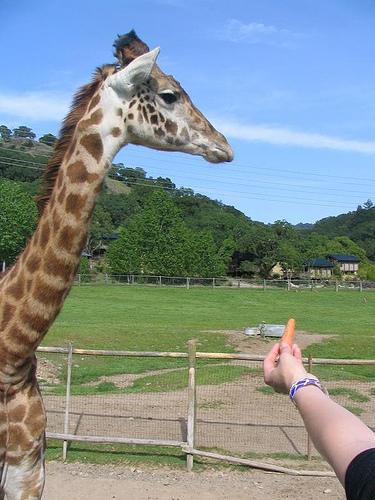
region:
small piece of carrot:
[278, 317, 297, 353]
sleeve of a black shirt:
[344, 445, 374, 498]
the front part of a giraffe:
[0, 29, 234, 499]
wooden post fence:
[34, 338, 374, 477]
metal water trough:
[241, 323, 286, 338]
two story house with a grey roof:
[293, 253, 359, 283]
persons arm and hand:
[263, 340, 373, 491]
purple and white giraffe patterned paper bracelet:
[288, 376, 329, 410]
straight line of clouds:
[0, 93, 373, 158]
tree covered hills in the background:
[0, 124, 373, 269]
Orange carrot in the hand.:
[274, 315, 296, 353]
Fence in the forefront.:
[32, 337, 372, 460]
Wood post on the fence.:
[181, 340, 197, 472]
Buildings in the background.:
[302, 249, 360, 281]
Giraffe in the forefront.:
[0, 26, 241, 496]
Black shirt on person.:
[338, 439, 373, 499]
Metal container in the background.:
[245, 320, 283, 339]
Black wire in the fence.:
[71, 352, 187, 440]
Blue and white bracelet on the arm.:
[288, 376, 328, 410]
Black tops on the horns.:
[111, 29, 146, 59]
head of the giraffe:
[96, 31, 249, 161]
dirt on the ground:
[102, 465, 158, 496]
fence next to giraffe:
[75, 339, 190, 440]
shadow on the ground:
[109, 441, 144, 460]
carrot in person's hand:
[263, 305, 304, 345]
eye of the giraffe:
[153, 82, 185, 115]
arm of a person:
[255, 335, 369, 457]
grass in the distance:
[120, 289, 188, 321]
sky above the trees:
[273, 63, 335, 111]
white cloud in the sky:
[248, 97, 327, 159]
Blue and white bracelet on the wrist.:
[287, 374, 325, 410]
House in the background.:
[301, 249, 359, 281]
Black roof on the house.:
[298, 250, 362, 267]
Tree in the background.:
[107, 190, 230, 284]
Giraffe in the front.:
[0, 25, 234, 497]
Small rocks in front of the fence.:
[45, 455, 243, 474]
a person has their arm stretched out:
[265, 331, 372, 491]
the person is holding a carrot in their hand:
[267, 321, 313, 391]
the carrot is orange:
[276, 314, 298, 352]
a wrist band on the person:
[285, 376, 325, 400]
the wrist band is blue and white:
[286, 373, 327, 396]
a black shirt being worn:
[336, 446, 373, 498]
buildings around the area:
[297, 252, 362, 286]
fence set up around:
[22, 263, 372, 462]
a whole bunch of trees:
[0, 159, 363, 274]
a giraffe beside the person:
[2, 28, 231, 496]